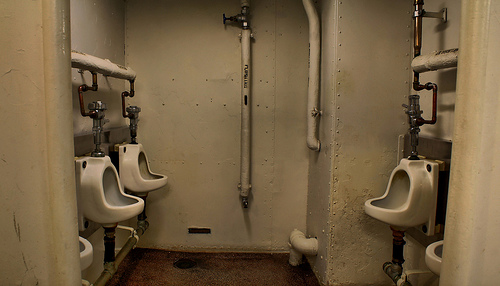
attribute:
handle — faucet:
[218, 3, 251, 28]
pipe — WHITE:
[280, 28, 340, 175]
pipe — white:
[221, 0, 254, 207]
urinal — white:
[358, 153, 435, 231]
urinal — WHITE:
[310, 131, 443, 246]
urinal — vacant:
[364, 156, 435, 227]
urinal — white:
[346, 131, 416, 232]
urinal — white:
[112, 136, 161, 200]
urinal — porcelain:
[359, 157, 440, 233]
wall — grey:
[117, 0, 308, 260]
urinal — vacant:
[117, 141, 172, 193]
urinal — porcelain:
[77, 157, 142, 219]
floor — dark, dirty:
[156, 243, 254, 278]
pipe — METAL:
[399, 3, 449, 131]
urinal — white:
[365, 156, 434, 233]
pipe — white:
[304, 11, 321, 150]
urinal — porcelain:
[351, 140, 445, 235]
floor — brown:
[121, 240, 304, 284]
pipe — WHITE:
[281, 230, 317, 272]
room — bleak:
[9, 9, 454, 283]